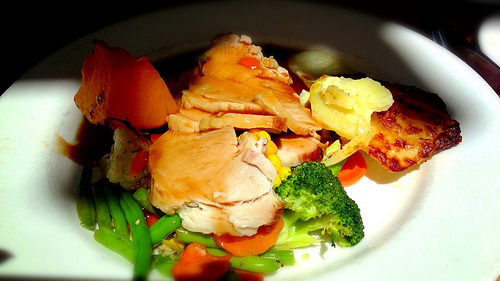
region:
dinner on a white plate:
[22, 16, 494, 278]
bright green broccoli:
[277, 163, 367, 253]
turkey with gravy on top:
[140, 26, 287, 236]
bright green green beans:
[77, 188, 176, 273]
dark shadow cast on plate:
[42, 12, 357, 87]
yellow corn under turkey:
[257, 123, 302, 190]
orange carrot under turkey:
[212, 218, 292, 260]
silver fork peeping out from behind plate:
[412, 21, 455, 67]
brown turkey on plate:
[42, 118, 109, 167]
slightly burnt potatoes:
[298, 61, 451, 170]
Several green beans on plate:
[85, 155, 175, 265]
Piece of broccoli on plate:
[235, 161, 363, 254]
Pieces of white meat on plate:
[173, 57, 238, 204]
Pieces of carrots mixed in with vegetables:
[178, 222, 300, 279]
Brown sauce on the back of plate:
[41, 105, 110, 178]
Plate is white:
[5, 63, 407, 263]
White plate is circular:
[18, 40, 471, 267]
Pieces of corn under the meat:
[263, 107, 305, 222]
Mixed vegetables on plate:
[85, 104, 324, 254]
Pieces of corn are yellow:
[201, 101, 345, 226]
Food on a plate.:
[55, 28, 454, 279]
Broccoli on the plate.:
[267, 136, 415, 272]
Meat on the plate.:
[125, 80, 333, 271]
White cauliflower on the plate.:
[307, 48, 382, 164]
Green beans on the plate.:
[42, 137, 129, 244]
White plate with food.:
[25, 47, 475, 276]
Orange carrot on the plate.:
[71, 34, 273, 161]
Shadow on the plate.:
[350, 20, 499, 170]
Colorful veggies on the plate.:
[152, 131, 368, 266]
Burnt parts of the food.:
[343, 61, 458, 200]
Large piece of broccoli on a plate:
[275, 160, 366, 250]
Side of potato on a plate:
[310, 75, 391, 142]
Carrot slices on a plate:
[74, 45, 176, 129]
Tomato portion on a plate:
[238, 57, 262, 77]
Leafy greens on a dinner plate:
[89, 190, 181, 280]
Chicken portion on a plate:
[150, 127, 285, 232]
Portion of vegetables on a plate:
[156, 233, 308, 278]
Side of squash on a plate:
[102, 125, 147, 192]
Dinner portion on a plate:
[75, 42, 451, 279]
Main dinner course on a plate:
[70, 34, 462, 279]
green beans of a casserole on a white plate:
[70, 120, 168, 280]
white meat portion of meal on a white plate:
[73, 38, 315, 235]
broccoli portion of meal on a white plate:
[270, 160, 362, 258]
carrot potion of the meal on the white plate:
[177, 225, 287, 278]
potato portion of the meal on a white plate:
[305, 64, 385, 164]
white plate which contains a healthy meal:
[0, 21, 495, 280]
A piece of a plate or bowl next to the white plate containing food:
[471, 0, 497, 68]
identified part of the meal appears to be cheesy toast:
[292, 24, 467, 174]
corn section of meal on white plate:
[242, 123, 295, 190]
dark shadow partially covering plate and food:
[0, 0, 417, 77]